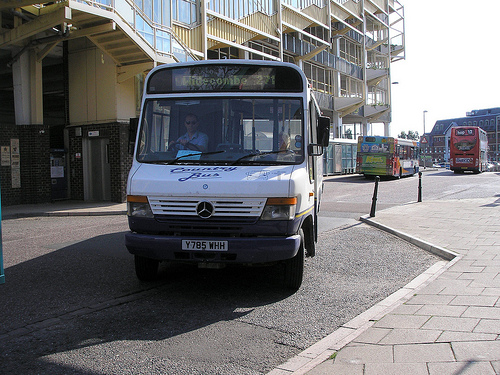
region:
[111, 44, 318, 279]
white european bus on street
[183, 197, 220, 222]
mercedes benz sign on a bus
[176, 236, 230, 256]
european license plate on bus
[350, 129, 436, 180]
multi-colored tour bus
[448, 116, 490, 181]
red double decker tour bus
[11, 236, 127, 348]
shadow of bus on the ground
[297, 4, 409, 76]
stair case on a building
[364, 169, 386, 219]
metal parking post on curb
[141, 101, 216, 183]
driver on the right side of the bus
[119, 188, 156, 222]
headlight on a bus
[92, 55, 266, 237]
The man is driving the vehicle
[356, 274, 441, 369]
The ground is stone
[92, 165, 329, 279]
The bus is white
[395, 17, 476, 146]
The sky is white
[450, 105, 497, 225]
This bus is two levels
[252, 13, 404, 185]
The building has many windows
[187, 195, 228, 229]
This is a Mercedes symbol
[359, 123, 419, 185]
This bus is colorful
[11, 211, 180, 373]
The road has shadows on it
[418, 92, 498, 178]
There is a building in the back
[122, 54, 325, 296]
a passenger bus is white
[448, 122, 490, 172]
the double decker bus is red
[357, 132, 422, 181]
a bus is stopped on the side of the road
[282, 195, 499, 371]
the sidewalk is tiled and gray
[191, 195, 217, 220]
a logo is on the front of the van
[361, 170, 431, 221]
posts are on the curb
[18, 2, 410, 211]
a large building is next to the street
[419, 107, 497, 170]
at the end of the road is a red brick building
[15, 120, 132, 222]
red bricks on the first floor of the building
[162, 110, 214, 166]
the bus driver is wearing sunglasses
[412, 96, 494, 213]
the bus is red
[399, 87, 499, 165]
the bus is red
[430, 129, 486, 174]
the bus is red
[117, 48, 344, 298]
a white public transportation vehicle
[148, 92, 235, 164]
driver of vehicle visible through windshield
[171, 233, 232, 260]
license plate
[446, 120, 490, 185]
two-story bus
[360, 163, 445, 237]
two posts on curb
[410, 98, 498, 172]
large building behind bus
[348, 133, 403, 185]
advertisements on back of bus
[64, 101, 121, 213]
entrance to building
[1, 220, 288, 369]
shadow on the road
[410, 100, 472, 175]
a tall pole near a building